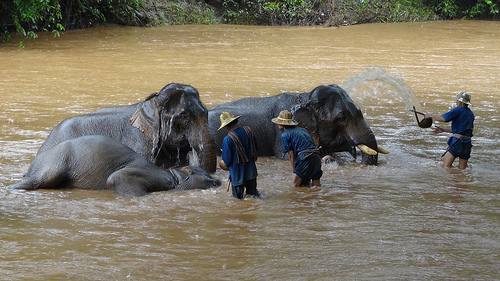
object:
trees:
[0, 0, 498, 49]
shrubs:
[0, 0, 494, 25]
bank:
[0, 12, 498, 31]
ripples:
[0, 20, 499, 279]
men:
[218, 111, 260, 201]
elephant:
[5, 135, 223, 198]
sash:
[297, 146, 322, 161]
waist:
[291, 145, 318, 158]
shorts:
[447, 137, 471, 161]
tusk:
[357, 144, 378, 155]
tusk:
[376, 145, 390, 154]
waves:
[385, 144, 431, 171]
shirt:
[441, 105, 475, 138]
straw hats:
[451, 91, 473, 107]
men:
[273, 110, 324, 190]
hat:
[271, 110, 299, 125]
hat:
[216, 112, 243, 132]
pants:
[230, 176, 261, 199]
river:
[1, 18, 499, 278]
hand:
[423, 113, 433, 119]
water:
[0, 22, 499, 280]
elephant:
[207, 83, 390, 165]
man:
[424, 92, 473, 170]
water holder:
[409, 106, 434, 129]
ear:
[129, 97, 160, 146]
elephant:
[23, 83, 217, 180]